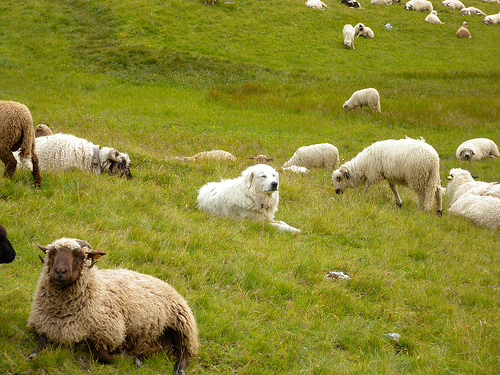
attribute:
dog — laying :
[199, 164, 299, 234]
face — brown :
[37, 238, 101, 291]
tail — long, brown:
[17, 115, 33, 175]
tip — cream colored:
[17, 153, 34, 170]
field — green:
[2, 100, 192, 175]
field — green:
[16, 164, 443, 330]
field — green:
[123, 102, 439, 320]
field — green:
[133, 50, 476, 145]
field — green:
[202, 283, 324, 367]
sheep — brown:
[1, 99, 55, 189]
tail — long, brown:
[13, 102, 33, 163]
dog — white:
[202, 161, 310, 233]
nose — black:
[269, 180, 279, 193]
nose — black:
[271, 180, 279, 188]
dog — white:
[195, 162, 302, 235]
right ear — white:
[240, 165, 253, 190]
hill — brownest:
[2, 1, 484, 128]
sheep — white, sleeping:
[12, 129, 133, 180]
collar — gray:
[91, 142, 102, 171]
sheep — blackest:
[339, 0, 363, 10]